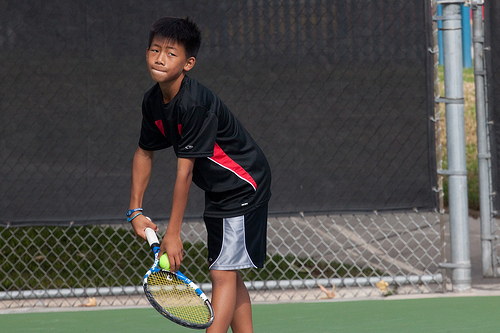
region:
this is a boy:
[195, 125, 252, 249]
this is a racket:
[144, 261, 187, 315]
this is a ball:
[146, 225, 201, 275]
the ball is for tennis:
[129, 184, 231, 307]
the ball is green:
[140, 184, 197, 301]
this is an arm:
[150, 195, 217, 259]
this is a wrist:
[136, 186, 199, 261]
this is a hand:
[172, 254, 186, 274]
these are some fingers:
[147, 254, 191, 258]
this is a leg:
[240, 274, 280, 331]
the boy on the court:
[101, 14, 262, 330]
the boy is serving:
[106, 15, 311, 325]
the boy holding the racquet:
[105, 6, 290, 327]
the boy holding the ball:
[107, 16, 322, 327]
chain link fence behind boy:
[5, 1, 480, 291]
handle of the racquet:
[140, 225, 165, 242]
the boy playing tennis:
[102, 13, 292, 332]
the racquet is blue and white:
[140, 245, 220, 327]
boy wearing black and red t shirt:
[114, 77, 286, 220]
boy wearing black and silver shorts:
[186, 170, 280, 283]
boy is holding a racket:
[101, 15, 264, 330]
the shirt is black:
[114, 78, 278, 243]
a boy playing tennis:
[127, 15, 269, 328]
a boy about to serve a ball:
[130, 210, 214, 330]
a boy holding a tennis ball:
[158, 233, 184, 273]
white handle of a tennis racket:
[143, 214, 158, 244]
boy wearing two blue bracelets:
[125, 205, 145, 220]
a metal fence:
[0, 3, 497, 305]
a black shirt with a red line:
[137, 84, 274, 214]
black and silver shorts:
[201, 203, 268, 270]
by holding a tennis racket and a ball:
[127, 207, 215, 328]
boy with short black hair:
[146, 14, 201, 84]